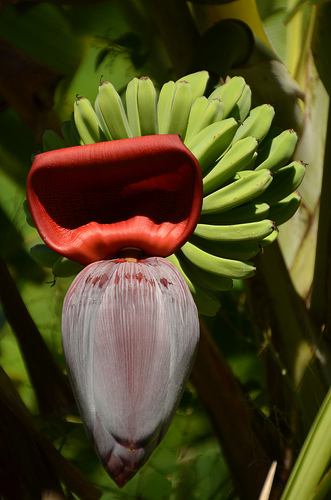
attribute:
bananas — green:
[21, 69, 307, 318]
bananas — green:
[72, 92, 106, 144]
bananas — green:
[95, 78, 133, 138]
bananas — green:
[124, 76, 158, 136]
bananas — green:
[250, 128, 300, 170]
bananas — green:
[192, 218, 277, 241]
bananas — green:
[152, 56, 330, 241]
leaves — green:
[171, 431, 213, 479]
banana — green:
[252, 126, 299, 173]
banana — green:
[181, 114, 240, 174]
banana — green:
[92, 73, 131, 141]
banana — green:
[69, 91, 109, 144]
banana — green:
[179, 237, 256, 278]